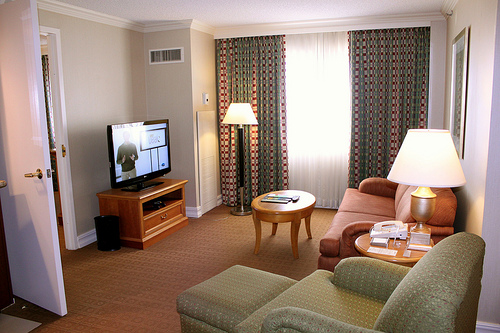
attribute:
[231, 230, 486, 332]
chair — brown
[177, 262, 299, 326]
ottoman — brown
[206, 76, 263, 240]
lamp — tall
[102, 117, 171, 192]
tv — flat screen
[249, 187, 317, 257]
table — oval, oval shaped, wooden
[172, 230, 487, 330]
chair — green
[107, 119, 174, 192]
television — on, flat screened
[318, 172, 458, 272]
sofa — red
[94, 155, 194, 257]
stand — brown, tv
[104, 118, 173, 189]
housing — black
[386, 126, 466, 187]
lamp shade — white